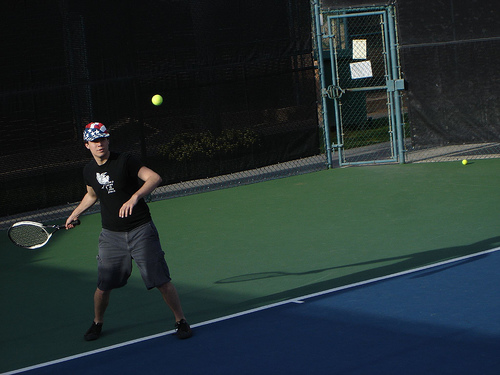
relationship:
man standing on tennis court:
[54, 122, 197, 340] [0, 162, 497, 374]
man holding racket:
[54, 121, 197, 339] [0, 217, 84, 253]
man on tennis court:
[54, 122, 197, 340] [150, 162, 497, 343]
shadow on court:
[208, 239, 484, 300] [185, 168, 485, 360]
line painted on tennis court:
[13, 243, 498, 374] [0, 162, 497, 374]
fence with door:
[1, 3, 498, 234] [313, 6, 407, 169]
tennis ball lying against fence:
[457, 156, 472, 168] [434, 123, 496, 163]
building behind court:
[0, 0, 371, 172] [155, 231, 499, 373]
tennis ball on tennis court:
[151, 93, 164, 106] [0, 162, 497, 374]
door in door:
[313, 6, 408, 165] [313, 6, 407, 169]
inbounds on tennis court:
[4, 245, 499, 373] [0, 162, 497, 374]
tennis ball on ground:
[461, 159, 468, 165] [5, 154, 497, 371]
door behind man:
[313, 6, 407, 169] [31, 92, 190, 339]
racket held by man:
[21, 197, 95, 248] [54, 121, 197, 339]